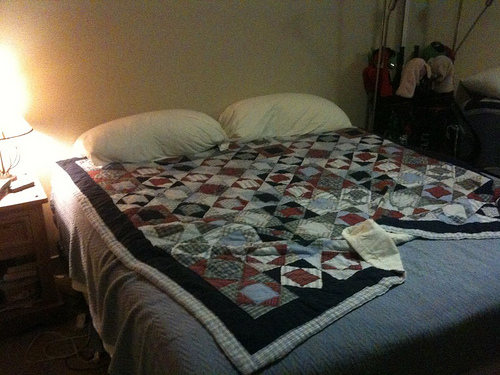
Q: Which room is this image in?
A: It is at the bedroom.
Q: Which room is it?
A: It is a bedroom.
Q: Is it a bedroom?
A: Yes, it is a bedroom.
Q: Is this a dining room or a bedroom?
A: It is a bedroom.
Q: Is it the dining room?
A: No, it is the bedroom.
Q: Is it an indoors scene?
A: Yes, it is indoors.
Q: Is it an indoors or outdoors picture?
A: It is indoors.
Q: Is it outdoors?
A: No, it is indoors.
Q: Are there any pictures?
A: No, there are no pictures.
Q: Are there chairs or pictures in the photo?
A: No, there are no pictures or chairs.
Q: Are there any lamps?
A: Yes, there is a lamp.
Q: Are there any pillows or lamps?
A: Yes, there is a lamp.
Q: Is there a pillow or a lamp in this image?
A: Yes, there is a lamp.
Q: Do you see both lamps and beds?
A: Yes, there are both a lamp and a bed.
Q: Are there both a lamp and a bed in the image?
A: Yes, there are both a lamp and a bed.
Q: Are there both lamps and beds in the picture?
A: Yes, there are both a lamp and a bed.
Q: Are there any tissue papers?
A: No, there are no tissue papers.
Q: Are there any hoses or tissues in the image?
A: No, there are no tissues or hoses.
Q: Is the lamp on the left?
A: Yes, the lamp is on the left of the image.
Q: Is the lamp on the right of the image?
A: No, the lamp is on the left of the image.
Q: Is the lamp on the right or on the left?
A: The lamp is on the left of the image.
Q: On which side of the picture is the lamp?
A: The lamp is on the left of the image.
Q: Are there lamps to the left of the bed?
A: Yes, there is a lamp to the left of the bed.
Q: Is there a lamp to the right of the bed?
A: No, the lamp is to the left of the bed.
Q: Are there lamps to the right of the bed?
A: No, the lamp is to the left of the bed.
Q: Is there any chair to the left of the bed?
A: No, there is a lamp to the left of the bed.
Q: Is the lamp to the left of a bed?
A: Yes, the lamp is to the left of a bed.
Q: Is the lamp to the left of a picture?
A: No, the lamp is to the left of a bed.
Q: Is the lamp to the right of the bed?
A: No, the lamp is to the left of the bed.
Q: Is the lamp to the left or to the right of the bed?
A: The lamp is to the left of the bed.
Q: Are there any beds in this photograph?
A: Yes, there is a bed.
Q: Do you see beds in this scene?
A: Yes, there is a bed.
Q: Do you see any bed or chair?
A: Yes, there is a bed.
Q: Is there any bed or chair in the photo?
A: Yes, there is a bed.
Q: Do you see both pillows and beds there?
A: Yes, there are both a bed and a pillow.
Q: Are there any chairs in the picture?
A: No, there are no chairs.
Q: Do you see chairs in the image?
A: No, there are no chairs.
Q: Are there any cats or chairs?
A: No, there are no chairs or cats.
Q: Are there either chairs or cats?
A: No, there are no chairs or cats.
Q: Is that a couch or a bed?
A: That is a bed.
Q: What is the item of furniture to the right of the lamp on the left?
A: The piece of furniture is a bed.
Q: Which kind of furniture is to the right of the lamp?
A: The piece of furniture is a bed.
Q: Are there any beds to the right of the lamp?
A: Yes, there is a bed to the right of the lamp.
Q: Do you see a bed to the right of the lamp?
A: Yes, there is a bed to the right of the lamp.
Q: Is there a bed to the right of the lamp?
A: Yes, there is a bed to the right of the lamp.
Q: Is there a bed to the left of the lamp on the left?
A: No, the bed is to the right of the lamp.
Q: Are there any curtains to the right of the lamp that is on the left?
A: No, there is a bed to the right of the lamp.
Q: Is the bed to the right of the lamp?
A: Yes, the bed is to the right of the lamp.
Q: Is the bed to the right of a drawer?
A: No, the bed is to the right of the lamp.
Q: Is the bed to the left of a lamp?
A: No, the bed is to the right of a lamp.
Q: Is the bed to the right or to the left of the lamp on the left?
A: The bed is to the right of the lamp.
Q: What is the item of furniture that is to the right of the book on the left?
A: The piece of furniture is a bed.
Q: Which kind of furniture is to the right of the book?
A: The piece of furniture is a bed.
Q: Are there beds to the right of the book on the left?
A: Yes, there is a bed to the right of the book.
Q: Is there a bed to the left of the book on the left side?
A: No, the bed is to the right of the book.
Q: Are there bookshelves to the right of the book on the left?
A: No, there is a bed to the right of the book.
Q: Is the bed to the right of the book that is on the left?
A: Yes, the bed is to the right of the book.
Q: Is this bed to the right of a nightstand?
A: No, the bed is to the right of the book.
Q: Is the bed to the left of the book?
A: No, the bed is to the right of the book.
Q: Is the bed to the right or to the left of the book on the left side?
A: The bed is to the right of the book.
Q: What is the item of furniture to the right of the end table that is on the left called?
A: The piece of furniture is a bed.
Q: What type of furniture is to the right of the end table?
A: The piece of furniture is a bed.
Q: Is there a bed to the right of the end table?
A: Yes, there is a bed to the right of the end table.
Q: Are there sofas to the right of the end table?
A: No, there is a bed to the right of the end table.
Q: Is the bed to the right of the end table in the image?
A: Yes, the bed is to the right of the end table.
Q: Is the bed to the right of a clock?
A: No, the bed is to the right of the end table.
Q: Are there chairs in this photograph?
A: No, there are no chairs.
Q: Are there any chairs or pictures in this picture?
A: No, there are no chairs or pictures.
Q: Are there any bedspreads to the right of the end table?
A: Yes, there is a bedspread to the right of the end table.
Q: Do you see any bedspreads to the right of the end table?
A: Yes, there is a bedspread to the right of the end table.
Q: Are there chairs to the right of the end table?
A: No, there is a bedspread to the right of the end table.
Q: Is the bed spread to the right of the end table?
A: Yes, the bed spread is to the right of the end table.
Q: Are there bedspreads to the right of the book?
A: Yes, there is a bedspread to the right of the book.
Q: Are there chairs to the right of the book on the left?
A: No, there is a bedspread to the right of the book.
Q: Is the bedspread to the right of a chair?
A: No, the bedspread is to the right of a book.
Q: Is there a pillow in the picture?
A: Yes, there is a pillow.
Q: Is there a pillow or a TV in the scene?
A: Yes, there is a pillow.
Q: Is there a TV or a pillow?
A: Yes, there is a pillow.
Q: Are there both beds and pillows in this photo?
A: Yes, there are both a pillow and a bed.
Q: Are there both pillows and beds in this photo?
A: Yes, there are both a pillow and a bed.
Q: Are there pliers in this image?
A: No, there are no pliers.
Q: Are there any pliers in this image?
A: No, there are no pliers.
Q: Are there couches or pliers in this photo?
A: No, there are no pliers or couches.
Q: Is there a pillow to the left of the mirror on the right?
A: Yes, there is a pillow to the left of the mirror.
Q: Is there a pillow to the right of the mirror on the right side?
A: No, the pillow is to the left of the mirror.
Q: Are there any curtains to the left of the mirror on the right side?
A: No, there is a pillow to the left of the mirror.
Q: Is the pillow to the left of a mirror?
A: Yes, the pillow is to the left of a mirror.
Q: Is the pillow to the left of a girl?
A: No, the pillow is to the left of a mirror.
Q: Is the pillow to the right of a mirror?
A: No, the pillow is to the left of a mirror.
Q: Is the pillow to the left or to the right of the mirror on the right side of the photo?
A: The pillow is to the left of the mirror.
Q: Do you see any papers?
A: No, there are no papers.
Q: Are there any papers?
A: No, there are no papers.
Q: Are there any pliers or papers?
A: No, there are no papers or pliers.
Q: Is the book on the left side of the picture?
A: Yes, the book is on the left of the image.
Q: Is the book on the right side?
A: No, the book is on the left of the image.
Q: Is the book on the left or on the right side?
A: The book is on the left of the image.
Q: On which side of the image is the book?
A: The book is on the left of the image.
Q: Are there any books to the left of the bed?
A: Yes, there is a book to the left of the bed.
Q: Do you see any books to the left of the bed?
A: Yes, there is a book to the left of the bed.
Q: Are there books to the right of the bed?
A: No, the book is to the left of the bed.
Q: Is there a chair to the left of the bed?
A: No, there is a book to the left of the bed.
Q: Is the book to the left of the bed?
A: Yes, the book is to the left of the bed.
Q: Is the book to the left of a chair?
A: No, the book is to the left of the bed.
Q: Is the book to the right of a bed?
A: No, the book is to the left of a bed.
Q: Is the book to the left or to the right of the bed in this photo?
A: The book is to the left of the bed.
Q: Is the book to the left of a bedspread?
A: Yes, the book is to the left of a bedspread.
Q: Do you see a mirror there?
A: Yes, there is a mirror.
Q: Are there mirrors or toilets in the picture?
A: Yes, there is a mirror.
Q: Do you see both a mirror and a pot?
A: No, there is a mirror but no pots.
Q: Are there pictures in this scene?
A: No, there are no pictures.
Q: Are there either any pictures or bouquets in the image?
A: No, there are no pictures or bouquets.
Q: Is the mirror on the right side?
A: Yes, the mirror is on the right of the image.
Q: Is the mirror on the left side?
A: No, the mirror is on the right of the image.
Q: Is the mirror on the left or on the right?
A: The mirror is on the right of the image.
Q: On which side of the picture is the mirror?
A: The mirror is on the right of the image.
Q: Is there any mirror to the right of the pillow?
A: Yes, there is a mirror to the right of the pillow.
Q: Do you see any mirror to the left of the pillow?
A: No, the mirror is to the right of the pillow.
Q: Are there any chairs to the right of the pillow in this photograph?
A: No, there is a mirror to the right of the pillow.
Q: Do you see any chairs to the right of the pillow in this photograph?
A: No, there is a mirror to the right of the pillow.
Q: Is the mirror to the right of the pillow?
A: Yes, the mirror is to the right of the pillow.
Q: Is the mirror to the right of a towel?
A: No, the mirror is to the right of the pillow.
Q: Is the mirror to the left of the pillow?
A: No, the mirror is to the right of the pillow.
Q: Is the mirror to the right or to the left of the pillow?
A: The mirror is to the right of the pillow.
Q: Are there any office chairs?
A: No, there are no office chairs.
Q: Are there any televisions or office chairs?
A: No, there are no office chairs or televisions.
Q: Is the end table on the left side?
A: Yes, the end table is on the left of the image.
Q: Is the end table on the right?
A: No, the end table is on the left of the image.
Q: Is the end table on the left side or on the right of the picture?
A: The end table is on the left of the image.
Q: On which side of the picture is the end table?
A: The end table is on the left of the image.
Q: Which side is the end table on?
A: The end table is on the left of the image.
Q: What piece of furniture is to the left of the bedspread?
A: The piece of furniture is an end table.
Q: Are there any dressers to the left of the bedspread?
A: No, there is an end table to the left of the bedspread.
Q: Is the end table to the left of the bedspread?
A: Yes, the end table is to the left of the bedspread.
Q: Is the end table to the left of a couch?
A: No, the end table is to the left of the bedspread.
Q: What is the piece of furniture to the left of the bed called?
A: The piece of furniture is an end table.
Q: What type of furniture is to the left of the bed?
A: The piece of furniture is an end table.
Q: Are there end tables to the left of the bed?
A: Yes, there is an end table to the left of the bed.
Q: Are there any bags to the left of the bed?
A: No, there is an end table to the left of the bed.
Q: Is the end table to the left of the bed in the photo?
A: Yes, the end table is to the left of the bed.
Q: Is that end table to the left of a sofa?
A: No, the end table is to the left of the bed.